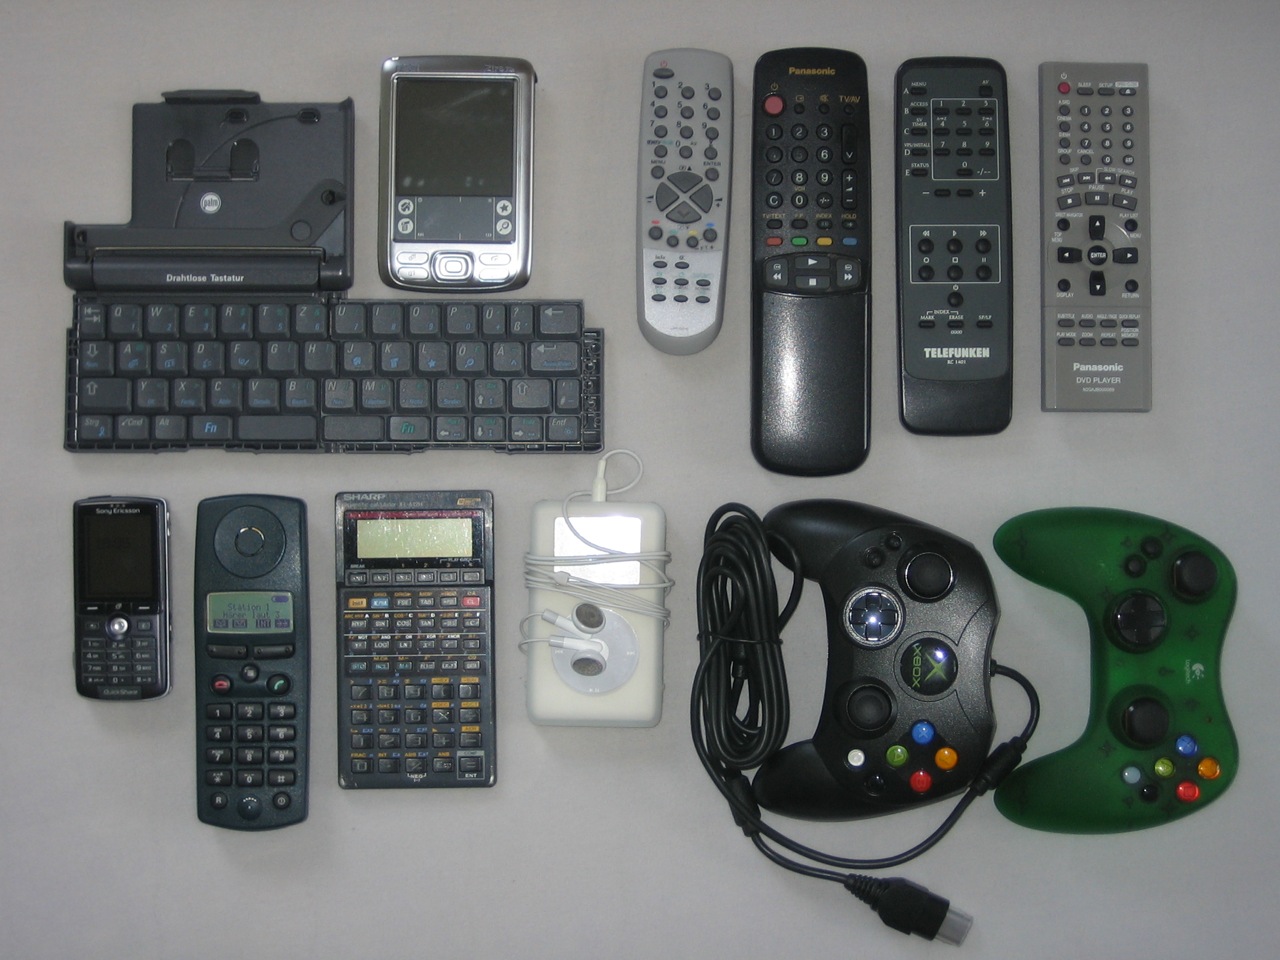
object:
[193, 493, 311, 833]
sheep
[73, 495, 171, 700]
cell phone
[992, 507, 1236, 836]
jpystick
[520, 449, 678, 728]
ipod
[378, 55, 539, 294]
cellphone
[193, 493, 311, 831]
cellphone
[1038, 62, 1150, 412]
remote control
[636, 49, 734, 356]
remote control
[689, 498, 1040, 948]
xbox controller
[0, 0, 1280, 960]
table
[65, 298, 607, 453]
keyboard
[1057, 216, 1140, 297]
keys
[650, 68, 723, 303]
keys